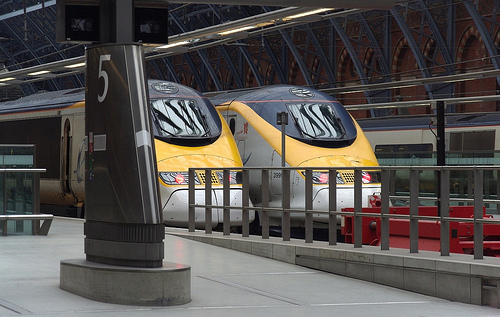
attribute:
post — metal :
[82, 0, 165, 270]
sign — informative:
[75, 41, 169, 268]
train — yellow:
[203, 84, 381, 240]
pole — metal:
[0, 166, 8, 236]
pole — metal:
[14, 169, 24, 231]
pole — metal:
[31, 173, 40, 233]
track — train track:
[253, 214, 463, 272]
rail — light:
[200, 85, 387, 230]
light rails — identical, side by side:
[145, 73, 430, 250]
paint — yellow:
[152, 137, 241, 186]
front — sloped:
[241, 82, 382, 215]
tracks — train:
[245, 208, 483, 256]